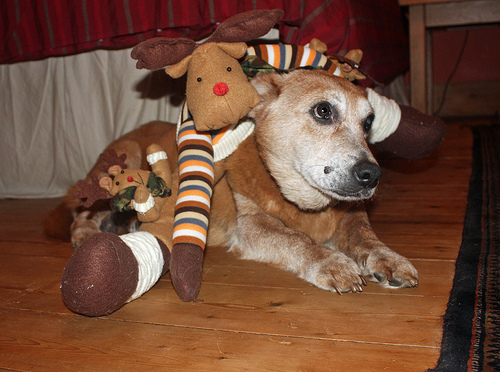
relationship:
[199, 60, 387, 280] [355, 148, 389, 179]
dog has nose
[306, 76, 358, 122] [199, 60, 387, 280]
eye of dog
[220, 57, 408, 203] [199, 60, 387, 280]
face of puppy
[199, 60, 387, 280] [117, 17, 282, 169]
puppy with rudolph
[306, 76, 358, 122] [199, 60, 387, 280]
eye of puppy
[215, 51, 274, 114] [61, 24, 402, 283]
ear of puppy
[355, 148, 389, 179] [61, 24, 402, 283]
nose of puppy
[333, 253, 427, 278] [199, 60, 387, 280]
paw of puppy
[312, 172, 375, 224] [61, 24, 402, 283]
mouth of puppy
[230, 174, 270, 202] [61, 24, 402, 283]
fur of puppy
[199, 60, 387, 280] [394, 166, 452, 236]
dog on floor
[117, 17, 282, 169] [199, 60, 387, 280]
animal on dog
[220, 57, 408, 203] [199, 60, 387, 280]
face of dog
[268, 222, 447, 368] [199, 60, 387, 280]
feet of dog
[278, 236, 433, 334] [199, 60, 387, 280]
claw of dog